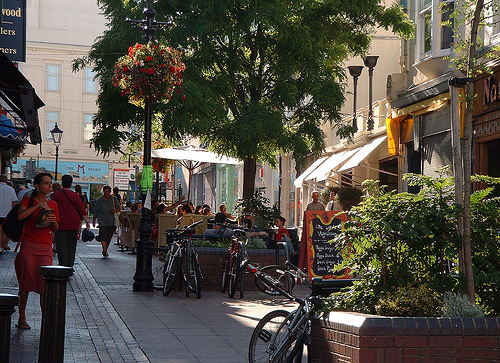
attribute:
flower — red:
[133, 41, 142, 50]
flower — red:
[145, 67, 154, 76]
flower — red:
[145, 53, 152, 63]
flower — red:
[151, 44, 158, 50]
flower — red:
[175, 65, 181, 74]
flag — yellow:
[382, 112, 413, 159]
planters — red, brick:
[162, 215, 289, 311]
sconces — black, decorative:
[361, 54, 379, 134]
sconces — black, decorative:
[346, 63, 364, 134]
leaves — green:
[324, 177, 426, 254]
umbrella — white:
[132, 144, 244, 166]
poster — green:
[137, 163, 159, 194]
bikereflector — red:
[244, 265, 260, 277]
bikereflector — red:
[185, 231, 195, 237]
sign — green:
[130, 162, 155, 194]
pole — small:
[130, 55, 159, 294]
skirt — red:
[12, 247, 45, 303]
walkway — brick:
[71, 260, 102, 361]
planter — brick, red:
[305, 298, 483, 361]